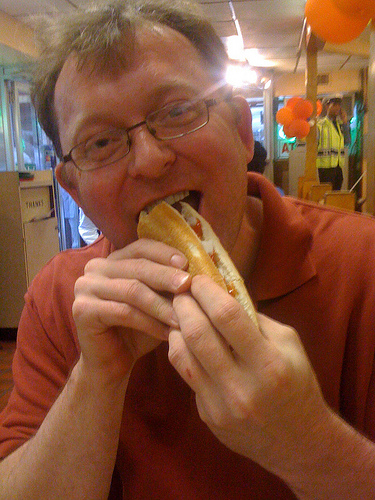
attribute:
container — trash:
[4, 167, 75, 269]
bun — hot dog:
[138, 199, 258, 330]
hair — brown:
[23, 0, 243, 212]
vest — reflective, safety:
[310, 116, 342, 173]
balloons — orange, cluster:
[274, 92, 323, 142]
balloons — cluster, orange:
[302, 4, 360, 45]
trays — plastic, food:
[16, 170, 35, 182]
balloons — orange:
[257, 98, 334, 141]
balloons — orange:
[273, 94, 311, 139]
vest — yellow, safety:
[313, 117, 347, 170]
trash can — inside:
[0, 169, 59, 342]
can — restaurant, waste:
[24, 170, 108, 241]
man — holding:
[36, 16, 308, 288]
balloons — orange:
[272, 92, 326, 141]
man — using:
[316, 96, 349, 190]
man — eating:
[33, 11, 347, 419]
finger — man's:
[163, 326, 210, 392]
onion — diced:
[200, 234, 216, 259]